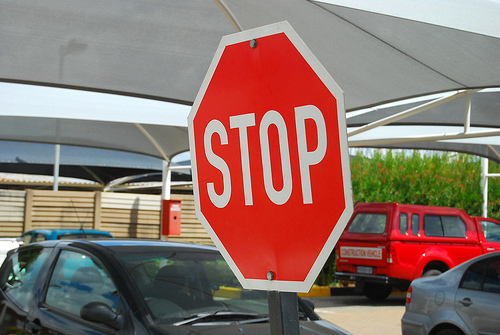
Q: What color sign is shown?
A: Red.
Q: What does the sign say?
A: Stop.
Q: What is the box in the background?
A: Red.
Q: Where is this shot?
A: Parking lot.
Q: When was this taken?
A: Daytime.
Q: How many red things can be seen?
A: 3.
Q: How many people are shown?
A: 0.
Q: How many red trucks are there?
A: 1.